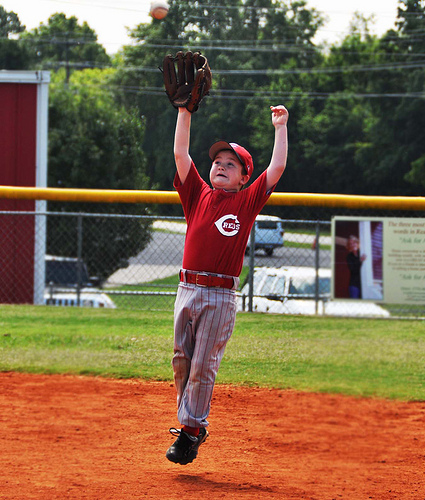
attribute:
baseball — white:
[143, 4, 176, 23]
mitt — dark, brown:
[152, 48, 222, 115]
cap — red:
[200, 137, 259, 178]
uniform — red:
[166, 156, 273, 284]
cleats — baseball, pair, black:
[155, 422, 216, 467]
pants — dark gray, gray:
[162, 267, 242, 434]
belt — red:
[174, 269, 237, 291]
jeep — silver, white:
[244, 210, 287, 257]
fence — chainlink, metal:
[2, 203, 177, 301]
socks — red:
[180, 424, 203, 436]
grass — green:
[5, 294, 172, 371]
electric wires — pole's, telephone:
[1, 0, 424, 106]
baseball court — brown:
[1, 309, 424, 496]